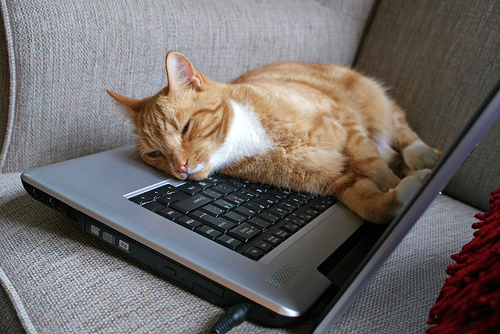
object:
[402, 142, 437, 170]
paw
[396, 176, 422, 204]
paw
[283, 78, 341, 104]
stripes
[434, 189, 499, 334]
fringe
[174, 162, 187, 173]
nose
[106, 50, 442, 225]
cat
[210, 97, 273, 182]
ruff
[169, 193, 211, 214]
black keys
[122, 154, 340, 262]
keyboard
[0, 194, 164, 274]
shadow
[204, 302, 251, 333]
cord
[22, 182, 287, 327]
laptop couch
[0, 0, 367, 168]
pillow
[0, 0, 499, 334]
chair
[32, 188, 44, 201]
holes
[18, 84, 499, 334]
laptop